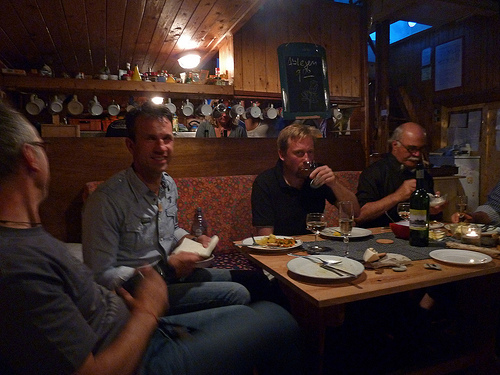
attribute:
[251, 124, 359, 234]
man — sitting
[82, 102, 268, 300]
man — sitting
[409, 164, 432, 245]
wine bottle — green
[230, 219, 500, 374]
table — wooden, brown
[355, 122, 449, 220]
man — eating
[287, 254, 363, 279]
plate — white, empty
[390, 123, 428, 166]
head — bald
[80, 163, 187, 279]
shirt — light blue, blue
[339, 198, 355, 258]
champagne glass — clear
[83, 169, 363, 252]
bench back — floral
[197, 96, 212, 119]
mug — hung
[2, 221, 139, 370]
shirt — gray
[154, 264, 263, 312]
jeans — blue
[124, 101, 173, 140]
hair — dark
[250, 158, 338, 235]
shirt — black